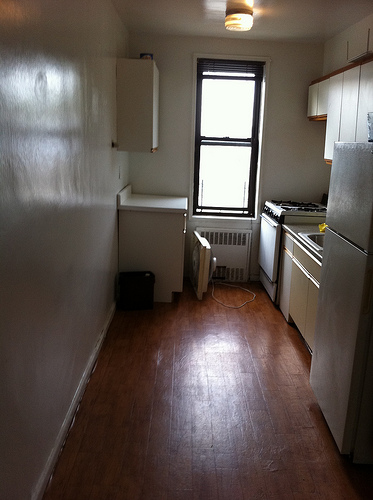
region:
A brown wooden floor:
[39, 280, 358, 497]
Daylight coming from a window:
[186, 54, 266, 222]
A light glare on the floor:
[175, 320, 261, 454]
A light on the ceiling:
[215, 5, 261, 43]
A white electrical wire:
[206, 267, 261, 316]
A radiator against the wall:
[189, 219, 258, 289]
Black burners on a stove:
[259, 191, 330, 225]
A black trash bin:
[105, 265, 164, 325]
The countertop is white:
[111, 178, 194, 214]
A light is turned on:
[215, 7, 258, 42]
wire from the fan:
[206, 266, 257, 318]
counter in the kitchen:
[112, 174, 192, 302]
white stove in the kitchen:
[258, 180, 331, 304]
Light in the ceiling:
[216, 7, 260, 39]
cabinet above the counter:
[113, 55, 166, 171]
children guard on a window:
[193, 179, 251, 210]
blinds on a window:
[199, 57, 264, 80]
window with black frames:
[196, 171, 256, 215]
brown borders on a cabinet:
[298, 72, 371, 122]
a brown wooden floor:
[114, 307, 320, 492]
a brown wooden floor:
[136, 344, 255, 458]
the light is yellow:
[215, 10, 260, 44]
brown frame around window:
[195, 65, 267, 231]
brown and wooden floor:
[104, 316, 269, 464]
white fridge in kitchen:
[317, 149, 370, 391]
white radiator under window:
[189, 221, 252, 286]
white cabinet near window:
[127, 55, 157, 160]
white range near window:
[246, 171, 341, 275]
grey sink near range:
[294, 199, 327, 253]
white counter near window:
[118, 167, 179, 219]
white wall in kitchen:
[27, 183, 85, 407]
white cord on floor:
[208, 275, 250, 313]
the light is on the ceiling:
[223, 7, 252, 32]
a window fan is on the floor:
[192, 231, 212, 300]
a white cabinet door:
[331, 74, 343, 151]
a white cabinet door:
[347, 76, 361, 124]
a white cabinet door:
[356, 72, 371, 111]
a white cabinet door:
[308, 78, 330, 107]